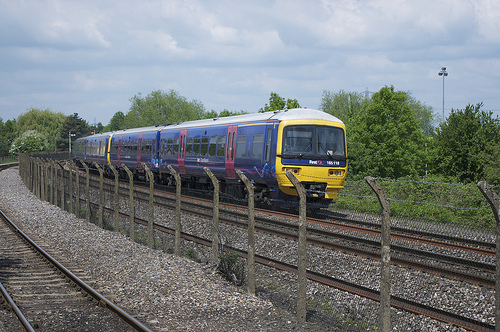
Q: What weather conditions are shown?
A: It is cloudy.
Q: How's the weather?
A: It is cloudy.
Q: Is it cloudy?
A: Yes, it is cloudy.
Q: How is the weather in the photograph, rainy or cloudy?
A: It is cloudy.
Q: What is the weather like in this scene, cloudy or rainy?
A: It is cloudy.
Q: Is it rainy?
A: No, it is cloudy.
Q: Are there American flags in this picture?
A: No, there are no American flags.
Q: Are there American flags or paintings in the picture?
A: No, there are no American flags or paintings.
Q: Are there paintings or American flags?
A: No, there are no American flags or paintings.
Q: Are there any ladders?
A: No, there are no ladders.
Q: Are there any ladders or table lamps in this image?
A: No, there are no ladders or table lamps.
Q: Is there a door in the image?
A: Yes, there are doors.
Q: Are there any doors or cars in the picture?
A: Yes, there are doors.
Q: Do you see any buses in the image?
A: No, there are no buses.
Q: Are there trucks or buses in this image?
A: No, there are no buses or trucks.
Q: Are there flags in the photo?
A: No, there are no flags.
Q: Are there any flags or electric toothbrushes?
A: No, there are no flags or electric toothbrushes.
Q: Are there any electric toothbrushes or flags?
A: No, there are no flags or electric toothbrushes.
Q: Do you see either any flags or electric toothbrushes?
A: No, there are no flags or electric toothbrushes.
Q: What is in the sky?
A: The clouds are in the sky.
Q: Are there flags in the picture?
A: No, there are no flags.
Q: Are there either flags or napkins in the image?
A: No, there are no flags or napkins.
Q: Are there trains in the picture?
A: Yes, there is a train.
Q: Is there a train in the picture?
A: Yes, there is a train.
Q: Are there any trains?
A: Yes, there is a train.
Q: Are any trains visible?
A: Yes, there is a train.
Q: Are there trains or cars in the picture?
A: Yes, there is a train.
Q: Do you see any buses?
A: No, there are no buses.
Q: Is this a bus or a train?
A: This is a train.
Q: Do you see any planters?
A: No, there are no planters.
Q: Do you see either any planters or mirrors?
A: No, there are no planters or mirrors.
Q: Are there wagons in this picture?
A: No, there are no wagons.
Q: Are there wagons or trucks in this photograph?
A: No, there are no wagons or trucks.